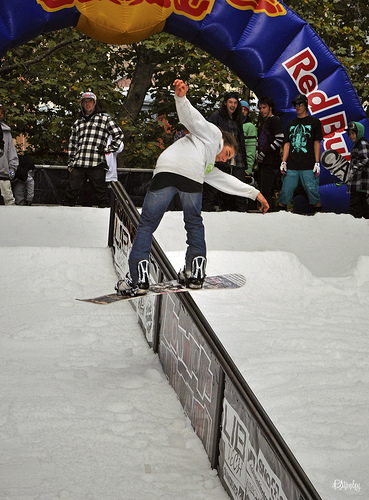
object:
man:
[115, 78, 269, 297]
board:
[76, 273, 246, 306]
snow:
[0, 204, 77, 500]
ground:
[0, 206, 367, 499]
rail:
[109, 182, 320, 499]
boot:
[114, 259, 149, 295]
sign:
[0, 0, 369, 214]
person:
[67, 91, 124, 209]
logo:
[281, 46, 351, 163]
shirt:
[153, 95, 260, 202]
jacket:
[67, 112, 124, 169]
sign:
[159, 276, 220, 465]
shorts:
[279, 169, 321, 205]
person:
[239, 101, 257, 208]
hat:
[240, 101, 249, 113]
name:
[331, 479, 361, 495]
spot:
[144, 463, 152, 473]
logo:
[204, 163, 214, 175]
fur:
[79, 104, 103, 122]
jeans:
[128, 186, 207, 282]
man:
[279, 94, 323, 215]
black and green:
[283, 116, 323, 170]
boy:
[344, 121, 369, 220]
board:
[320, 149, 351, 187]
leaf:
[142, 44, 155, 51]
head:
[215, 130, 239, 162]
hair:
[222, 131, 239, 157]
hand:
[173, 79, 187, 98]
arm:
[176, 96, 215, 135]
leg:
[128, 186, 176, 284]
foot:
[173, 266, 205, 293]